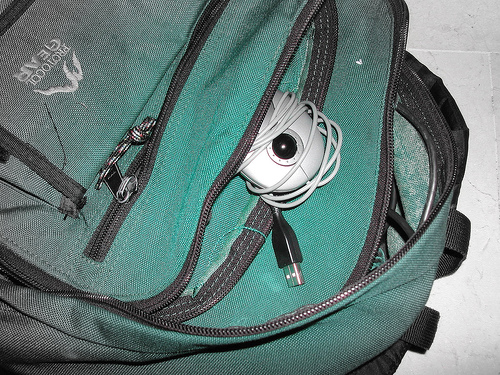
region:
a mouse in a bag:
[220, 71, 350, 216]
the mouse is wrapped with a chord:
[220, 71, 355, 221]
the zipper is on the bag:
[80, 145, 145, 210]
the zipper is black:
[85, 10, 215, 255]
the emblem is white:
[5, 35, 97, 122]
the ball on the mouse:
[260, 125, 310, 170]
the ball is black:
[260, 120, 307, 175]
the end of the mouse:
[245, 200, 325, 302]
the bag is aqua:
[65, 7, 446, 324]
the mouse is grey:
[200, 76, 360, 227]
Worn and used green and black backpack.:
[1, 0, 498, 367]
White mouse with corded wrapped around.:
[225, 83, 342, 210]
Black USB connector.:
[260, 202, 317, 299]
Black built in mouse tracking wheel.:
[264, 126, 306, 163]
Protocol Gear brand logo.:
[6, 25, 91, 107]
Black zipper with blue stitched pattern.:
[297, 1, 337, 104]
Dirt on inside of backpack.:
[378, 80, 451, 240]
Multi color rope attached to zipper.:
[85, 104, 162, 199]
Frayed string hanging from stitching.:
[37, 98, 77, 183]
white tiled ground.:
[403, 2, 497, 374]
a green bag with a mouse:
[8, 15, 460, 346]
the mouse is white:
[215, 85, 370, 315]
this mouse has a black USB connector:
[261, 192, 326, 297]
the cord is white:
[215, 90, 341, 200]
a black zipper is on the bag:
[86, 15, 163, 280]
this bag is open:
[348, 36, 466, 300]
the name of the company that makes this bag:
[1, 25, 104, 135]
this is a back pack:
[55, 23, 454, 338]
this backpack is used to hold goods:
[60, 36, 433, 334]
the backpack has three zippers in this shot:
[18, 14, 433, 359]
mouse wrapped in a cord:
[218, 82, 363, 220]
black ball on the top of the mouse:
[268, 131, 307, 164]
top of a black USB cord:
[270, 218, 309, 294]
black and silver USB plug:
[271, 203, 308, 290]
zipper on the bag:
[103, 165, 133, 202]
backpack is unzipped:
[334, 71, 473, 284]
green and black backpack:
[0, 0, 470, 374]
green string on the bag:
[203, 213, 275, 267]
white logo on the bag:
[12, 38, 97, 103]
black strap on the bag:
[396, 308, 446, 355]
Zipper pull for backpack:
[93, 114, 162, 208]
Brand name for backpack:
[15, 33, 88, 103]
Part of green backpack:
[291, 341, 364, 363]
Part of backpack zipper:
[99, 209, 119, 257]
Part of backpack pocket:
[88, 16, 146, 77]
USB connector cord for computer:
[268, 216, 310, 292]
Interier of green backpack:
[401, 136, 421, 188]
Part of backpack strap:
[450, 211, 466, 261]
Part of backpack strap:
[411, 316, 432, 346]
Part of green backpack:
[239, 14, 259, 76]